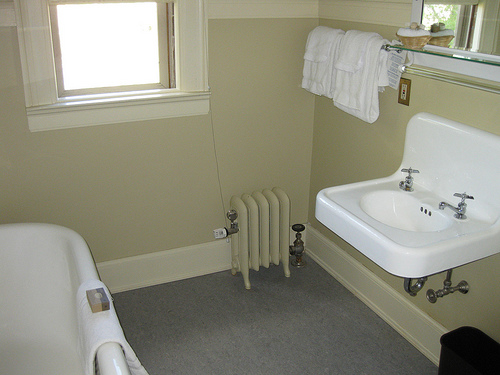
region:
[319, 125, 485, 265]
this is the toilet sink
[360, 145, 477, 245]
the sink is white in color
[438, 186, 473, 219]
this is the tap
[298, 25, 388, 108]
these are the towels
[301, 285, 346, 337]
this is the floor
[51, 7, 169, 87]
this is the window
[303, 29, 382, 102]
the towels are white in color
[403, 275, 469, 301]
these are the pipes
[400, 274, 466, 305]
the pipes are metallic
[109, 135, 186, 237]
this is the wall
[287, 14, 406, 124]
white towels on holder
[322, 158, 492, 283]
the sink is white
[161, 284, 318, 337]
gray color on floor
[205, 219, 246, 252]
large white screw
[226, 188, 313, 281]
small heater on ground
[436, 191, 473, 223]
shiny silver faucet in sink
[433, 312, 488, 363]
black waste basket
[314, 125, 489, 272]
porcelain white sink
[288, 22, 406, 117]
folded white towels on wall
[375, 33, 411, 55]
rack for white towels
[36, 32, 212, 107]
large window in the bathroom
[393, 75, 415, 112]
small brown socket on wall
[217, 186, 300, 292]
Radiator against the wall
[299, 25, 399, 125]
Towels hanging from towel rack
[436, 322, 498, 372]
Black trash bin under sink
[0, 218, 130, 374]
White tub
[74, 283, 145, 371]
Bath mat hanging from tub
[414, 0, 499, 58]
Mirror over the sink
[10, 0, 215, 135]
Window trimmed with white baseboard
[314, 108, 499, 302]
Simple white sink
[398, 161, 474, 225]
Two faucets at the sink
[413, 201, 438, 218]
Three drain holes in sink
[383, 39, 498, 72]
A towel rack over a sink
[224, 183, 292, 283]
A small heater on the floor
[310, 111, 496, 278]
A white tile sink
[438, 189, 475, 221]
A metal faucet for cold water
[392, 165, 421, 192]
A metal faucet for hot water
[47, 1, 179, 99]
A small window bathroom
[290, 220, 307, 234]
A valve for adjusting heat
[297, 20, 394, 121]
A white towel on a rack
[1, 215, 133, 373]
A white metal bathtub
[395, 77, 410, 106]
A wall switch for the lights